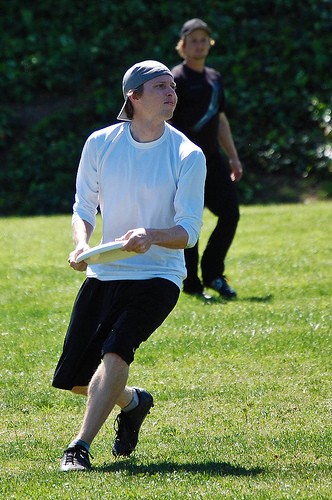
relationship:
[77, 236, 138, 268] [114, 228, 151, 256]
frisbee in hand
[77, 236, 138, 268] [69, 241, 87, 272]
frisbee in hand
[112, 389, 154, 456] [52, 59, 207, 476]
cleat on man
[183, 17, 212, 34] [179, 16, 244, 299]
hat on man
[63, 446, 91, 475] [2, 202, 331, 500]
cleat on grass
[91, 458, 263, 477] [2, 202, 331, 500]
shadow on grass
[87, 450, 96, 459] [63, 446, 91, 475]
lace on cleat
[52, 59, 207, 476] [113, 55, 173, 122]
man wearing a hat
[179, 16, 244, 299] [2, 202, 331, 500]
man in grass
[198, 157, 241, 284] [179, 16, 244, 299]
pants on man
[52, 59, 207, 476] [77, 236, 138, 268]
man holding onto frisbee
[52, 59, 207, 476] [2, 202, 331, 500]
man standing on grass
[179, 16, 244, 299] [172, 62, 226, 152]
man wearing a shirt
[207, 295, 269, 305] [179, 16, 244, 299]
shadow of man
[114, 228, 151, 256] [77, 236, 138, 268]
hand on frisbee